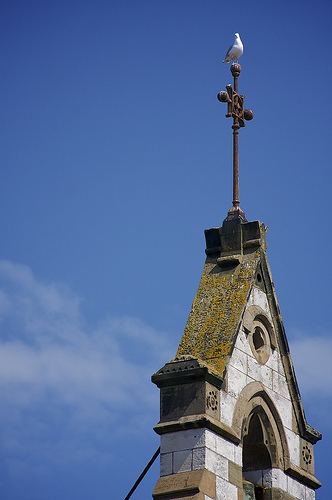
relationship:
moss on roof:
[169, 251, 258, 371] [151, 221, 324, 438]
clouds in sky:
[1, 258, 330, 467] [2, 2, 330, 500]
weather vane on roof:
[217, 62, 252, 212] [151, 221, 324, 438]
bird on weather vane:
[222, 31, 243, 63] [217, 62, 252, 212]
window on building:
[251, 329, 264, 350] [125, 62, 323, 495]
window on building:
[239, 413, 272, 499] [125, 62, 323, 495]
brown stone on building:
[154, 470, 217, 500] [125, 62, 323, 495]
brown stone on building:
[226, 461, 243, 500] [125, 62, 323, 495]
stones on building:
[239, 358, 274, 388] [125, 62, 323, 495]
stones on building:
[156, 428, 215, 451] [125, 62, 323, 495]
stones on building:
[189, 449, 218, 466] [125, 62, 323, 495]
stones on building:
[261, 390, 293, 413] [125, 62, 323, 495]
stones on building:
[261, 468, 286, 491] [125, 62, 323, 495]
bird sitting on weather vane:
[222, 31, 243, 63] [217, 62, 252, 212]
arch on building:
[233, 391, 291, 499] [125, 62, 323, 495]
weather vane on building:
[217, 62, 252, 212] [125, 62, 323, 495]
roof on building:
[151, 221, 324, 438] [125, 62, 323, 495]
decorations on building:
[207, 391, 218, 410] [125, 62, 323, 495]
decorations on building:
[303, 444, 313, 464] [125, 62, 323, 495]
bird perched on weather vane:
[222, 31, 243, 63] [217, 62, 252, 212]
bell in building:
[243, 477, 256, 500] [125, 62, 323, 495]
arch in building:
[233, 391, 291, 499] [125, 62, 323, 495]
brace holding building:
[125, 445, 160, 500] [125, 62, 323, 495]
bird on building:
[222, 31, 243, 63] [125, 62, 323, 495]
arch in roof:
[233, 391, 291, 499] [151, 221, 324, 438]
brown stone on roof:
[154, 470, 217, 500] [151, 221, 324, 438]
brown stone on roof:
[226, 461, 243, 500] [151, 221, 324, 438]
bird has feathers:
[222, 31, 243, 63] [224, 43, 240, 61]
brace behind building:
[125, 445, 160, 500] [125, 62, 323, 495]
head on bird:
[231, 33, 241, 43] [222, 31, 243, 63]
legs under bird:
[233, 58, 238, 67] [222, 31, 243, 63]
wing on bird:
[226, 45, 234, 57] [222, 31, 243, 63]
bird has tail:
[222, 31, 243, 63] [222, 57, 231, 62]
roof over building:
[151, 221, 324, 438] [125, 62, 323, 495]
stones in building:
[156, 428, 215, 451] [125, 62, 323, 495]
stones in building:
[189, 449, 218, 466] [125, 62, 323, 495]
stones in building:
[239, 358, 274, 388] [125, 62, 323, 495]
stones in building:
[261, 390, 293, 413] [125, 62, 323, 495]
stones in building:
[261, 468, 286, 491] [125, 62, 323, 495]